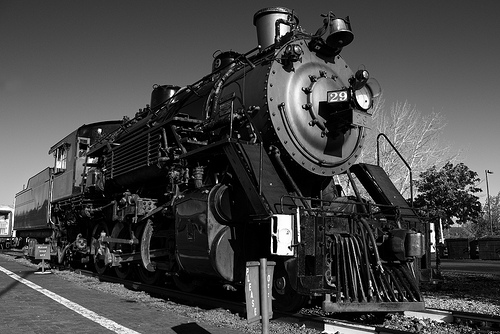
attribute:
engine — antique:
[101, 10, 413, 312]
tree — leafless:
[393, 134, 490, 253]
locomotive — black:
[0, 3, 440, 331]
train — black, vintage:
[4, 2, 445, 321]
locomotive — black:
[22, 35, 468, 328]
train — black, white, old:
[32, 24, 498, 304]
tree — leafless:
[367, 86, 440, 188]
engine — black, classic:
[175, 6, 429, 314]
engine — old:
[10, 4, 428, 316]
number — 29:
[326, 87, 352, 106]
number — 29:
[323, 85, 347, 103]